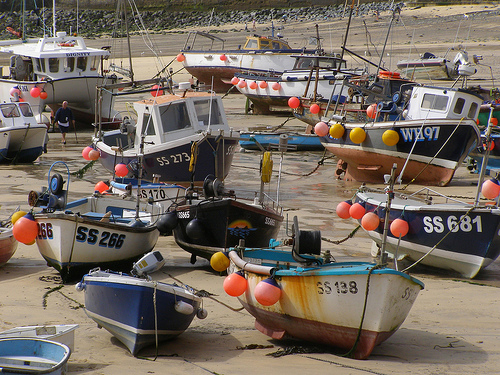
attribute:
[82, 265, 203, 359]
boat — blue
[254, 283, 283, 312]
buoy — pink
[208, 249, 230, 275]
buoy — yellow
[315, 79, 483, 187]
boat — blue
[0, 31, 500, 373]
boats — several, ss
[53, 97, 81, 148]
person — walking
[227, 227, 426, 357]
boat — named, white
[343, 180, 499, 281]
boat — ss681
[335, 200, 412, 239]
balloons — four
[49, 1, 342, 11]
grass — green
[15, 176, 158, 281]
boat — ss266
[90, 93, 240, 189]
boat — ss273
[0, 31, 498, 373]
ground — dirty